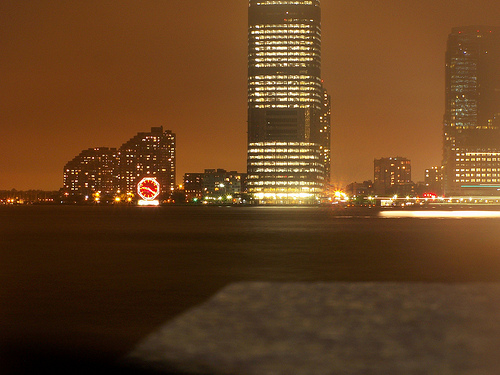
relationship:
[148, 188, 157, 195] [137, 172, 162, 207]
hands in clock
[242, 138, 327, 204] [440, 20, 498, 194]
bottom of building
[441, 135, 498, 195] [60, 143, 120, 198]
bottom of building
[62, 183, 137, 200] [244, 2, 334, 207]
bottom of building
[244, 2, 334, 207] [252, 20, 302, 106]
building with office lights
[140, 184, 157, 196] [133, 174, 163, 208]
hands on clock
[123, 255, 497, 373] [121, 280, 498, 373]
asphalt top on top of asphalt top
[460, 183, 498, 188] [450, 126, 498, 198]
light on front of building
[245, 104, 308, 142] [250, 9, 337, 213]
parking lots in middle of building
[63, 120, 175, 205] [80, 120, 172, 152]
building has roof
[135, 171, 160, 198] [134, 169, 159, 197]
hands on clock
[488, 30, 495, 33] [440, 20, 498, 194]
red light on building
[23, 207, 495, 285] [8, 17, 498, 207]
water on side of buildings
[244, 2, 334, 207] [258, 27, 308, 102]
building has lights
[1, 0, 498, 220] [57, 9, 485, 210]
skyline has lights